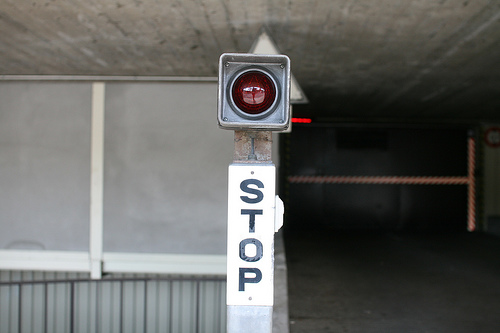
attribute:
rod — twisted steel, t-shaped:
[282, 138, 476, 233]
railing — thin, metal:
[1, 269, 227, 331]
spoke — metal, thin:
[69, 280, 74, 331]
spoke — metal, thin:
[16, 282, 21, 331]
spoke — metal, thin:
[43, 281, 47, 331]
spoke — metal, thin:
[118, 279, 124, 331]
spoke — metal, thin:
[167, 280, 173, 331]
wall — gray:
[1, 78, 233, 331]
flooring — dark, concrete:
[284, 213, 483, 330]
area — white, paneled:
[1, 79, 233, 331]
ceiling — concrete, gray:
[2, 1, 484, 123]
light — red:
[211, 57, 310, 138]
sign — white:
[230, 168, 275, 310]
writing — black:
[220, 179, 286, 309]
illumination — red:
[293, 109, 308, 138]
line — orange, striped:
[284, 175, 465, 195]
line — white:
[79, 75, 122, 279]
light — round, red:
[198, 43, 300, 138]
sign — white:
[224, 157, 275, 314]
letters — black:
[237, 173, 263, 292]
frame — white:
[16, 246, 173, 288]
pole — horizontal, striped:
[286, 172, 453, 192]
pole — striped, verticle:
[458, 137, 484, 240]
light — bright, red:
[285, 116, 311, 123]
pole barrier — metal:
[281, 137, 474, 233]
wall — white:
[0, 77, 292, 331]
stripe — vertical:
[88, 83, 108, 286]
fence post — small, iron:
[15, 281, 22, 331]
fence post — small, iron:
[42, 281, 49, 331]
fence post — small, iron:
[68, 282, 77, 331]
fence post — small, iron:
[117, 277, 125, 329]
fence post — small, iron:
[142, 274, 151, 331]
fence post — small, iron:
[166, 272, 175, 331]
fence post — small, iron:
[193, 277, 203, 331]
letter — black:
[241, 175, 264, 204]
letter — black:
[239, 209, 263, 229]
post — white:
[222, 160, 274, 330]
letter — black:
[236, 236, 265, 263]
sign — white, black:
[225, 158, 275, 331]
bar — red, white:
[292, 175, 474, 185]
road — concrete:
[281, 229, 484, 331]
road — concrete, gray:
[275, 239, 484, 329]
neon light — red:
[285, 116, 309, 123]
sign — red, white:
[484, 130, 500, 144]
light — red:
[217, 51, 289, 130]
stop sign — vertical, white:
[226, 163, 276, 328]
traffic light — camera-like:
[217, 51, 292, 132]